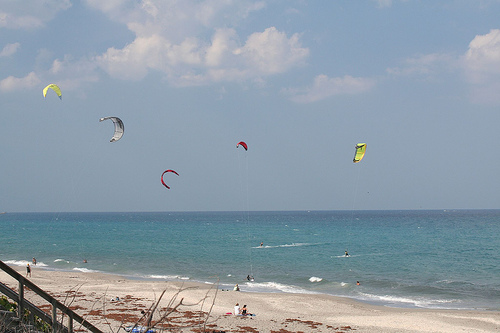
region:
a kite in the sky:
[156, 163, 184, 190]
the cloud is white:
[124, 32, 275, 103]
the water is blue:
[411, 229, 481, 281]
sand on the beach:
[369, 306, 411, 328]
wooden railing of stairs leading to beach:
[0, 256, 110, 331]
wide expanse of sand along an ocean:
[0, 268, 499, 331]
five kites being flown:
[38, 79, 370, 195]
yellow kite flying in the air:
[348, 131, 378, 173]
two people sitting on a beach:
[230, 296, 252, 322]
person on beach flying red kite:
[230, 136, 259, 288]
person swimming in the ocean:
[348, 274, 366, 296]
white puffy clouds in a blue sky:
[2, 27, 497, 108]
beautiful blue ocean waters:
[3, 209, 498, 310]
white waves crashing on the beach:
[0, 256, 47, 271]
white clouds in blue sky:
[130, 88, 182, 145]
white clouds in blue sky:
[204, 29, 255, 80]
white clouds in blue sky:
[101, 99, 156, 149]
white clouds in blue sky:
[105, 133, 172, 177]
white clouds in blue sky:
[370, 81, 422, 112]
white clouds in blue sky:
[28, 165, 75, 199]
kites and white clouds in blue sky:
[180, 65, 254, 159]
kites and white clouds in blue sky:
[355, 135, 385, 153]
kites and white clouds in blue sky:
[366, 45, 404, 85]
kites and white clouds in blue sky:
[180, 51, 230, 138]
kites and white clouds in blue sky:
[93, 85, 163, 149]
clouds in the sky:
[172, 15, 317, 112]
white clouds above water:
[197, 33, 334, 68]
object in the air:
[219, 108, 268, 177]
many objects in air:
[1, 63, 446, 240]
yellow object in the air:
[13, 72, 90, 127]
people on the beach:
[215, 290, 270, 331]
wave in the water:
[269, 253, 363, 308]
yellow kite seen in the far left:
[35, 78, 77, 109]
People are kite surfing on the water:
[183, 216, 406, 304]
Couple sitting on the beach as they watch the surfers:
[233, 295, 253, 324]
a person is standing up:
[238, 301, 253, 324]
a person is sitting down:
[235, 286, 241, 293]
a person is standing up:
[21, 259, 38, 279]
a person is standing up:
[30, 253, 38, 266]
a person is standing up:
[240, 270, 252, 284]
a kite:
[160, 166, 175, 193]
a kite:
[352, 135, 369, 163]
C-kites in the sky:
[32, 78, 386, 208]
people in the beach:
[18, 227, 355, 325]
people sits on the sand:
[223, 296, 257, 324]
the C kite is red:
[231, 136, 252, 153]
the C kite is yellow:
[351, 136, 372, 166]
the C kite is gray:
[91, 111, 133, 147]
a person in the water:
[336, 244, 353, 265]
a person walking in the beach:
[17, 258, 41, 285]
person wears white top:
[231, 298, 241, 315]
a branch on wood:
[83, 276, 218, 331]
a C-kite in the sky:
[33, 73, 69, 105]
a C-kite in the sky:
[96, 106, 131, 148]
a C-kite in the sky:
[154, 163, 186, 191]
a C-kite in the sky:
[231, 136, 251, 159]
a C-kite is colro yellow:
[347, 138, 374, 165]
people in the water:
[253, 235, 366, 268]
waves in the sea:
[363, 283, 453, 317]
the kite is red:
[153, 162, 184, 192]